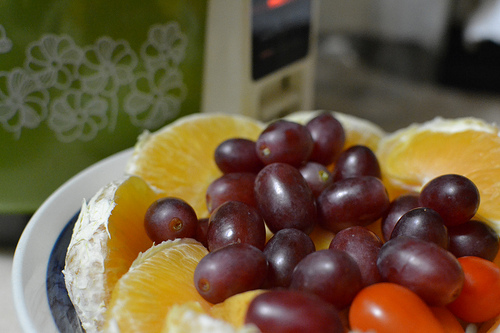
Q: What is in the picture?
A: Fruits.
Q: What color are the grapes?
A: Purple.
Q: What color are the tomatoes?
A: Red.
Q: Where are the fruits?
A: On a plate.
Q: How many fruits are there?
A: Three.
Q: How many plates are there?
A: One.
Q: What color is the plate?
A: Blue and white.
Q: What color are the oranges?
A: Orange.